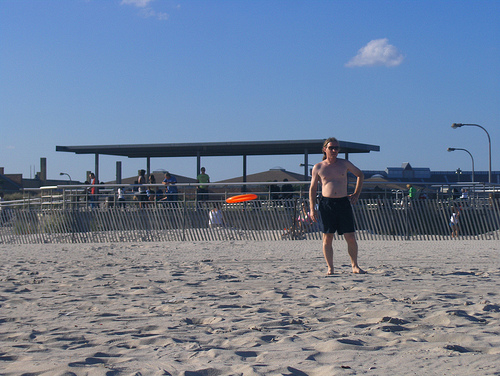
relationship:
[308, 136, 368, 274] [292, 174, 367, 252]
man wearing shorts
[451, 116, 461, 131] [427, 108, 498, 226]
lamp on pole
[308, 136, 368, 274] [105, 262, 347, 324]
man on beach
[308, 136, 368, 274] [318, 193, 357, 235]
man wearing shorts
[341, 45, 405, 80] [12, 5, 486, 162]
cloud in sky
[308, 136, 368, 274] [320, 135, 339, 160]
man has head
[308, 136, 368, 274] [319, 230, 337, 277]
man has leg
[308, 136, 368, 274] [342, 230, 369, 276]
man has leg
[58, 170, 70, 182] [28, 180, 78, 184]
pole by building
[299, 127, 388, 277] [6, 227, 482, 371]
man standing on beach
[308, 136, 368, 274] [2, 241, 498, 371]
man on sand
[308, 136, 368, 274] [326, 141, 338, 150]
man wears sunglasses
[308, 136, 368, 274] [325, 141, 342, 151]
man wears sunglasses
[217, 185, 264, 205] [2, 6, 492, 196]
freesbee in air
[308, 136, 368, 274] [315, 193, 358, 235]
man wears shorts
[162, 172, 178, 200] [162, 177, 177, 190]
man wears shirt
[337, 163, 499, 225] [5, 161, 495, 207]
building on background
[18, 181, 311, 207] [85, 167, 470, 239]
railing front crowd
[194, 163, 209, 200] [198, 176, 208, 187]
man wears shirt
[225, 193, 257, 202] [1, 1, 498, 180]
freesbee in sky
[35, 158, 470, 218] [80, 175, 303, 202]
crowd on boardwalk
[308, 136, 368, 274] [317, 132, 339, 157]
man has hair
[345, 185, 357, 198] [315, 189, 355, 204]
hand on waist